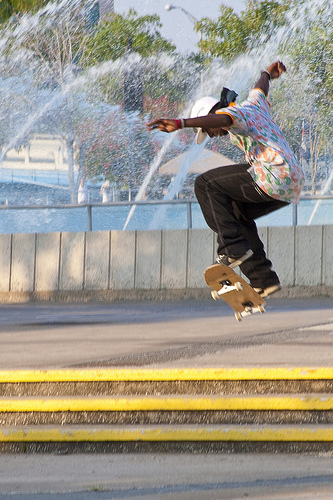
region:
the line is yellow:
[187, 432, 192, 433]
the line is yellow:
[180, 430, 189, 442]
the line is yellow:
[174, 436, 180, 442]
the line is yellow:
[199, 431, 204, 440]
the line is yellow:
[198, 429, 207, 438]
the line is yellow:
[194, 424, 205, 442]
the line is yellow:
[195, 432, 200, 434]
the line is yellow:
[191, 428, 200, 437]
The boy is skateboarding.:
[132, 54, 317, 328]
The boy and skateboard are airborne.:
[128, 62, 319, 326]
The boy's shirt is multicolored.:
[212, 82, 314, 214]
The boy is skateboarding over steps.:
[1, 356, 331, 461]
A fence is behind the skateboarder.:
[0, 218, 330, 304]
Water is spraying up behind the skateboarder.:
[0, 3, 332, 227]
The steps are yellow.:
[0, 360, 331, 456]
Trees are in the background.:
[0, 0, 332, 98]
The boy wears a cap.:
[177, 78, 232, 151]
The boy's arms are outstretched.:
[127, 43, 295, 156]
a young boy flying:
[141, 54, 307, 451]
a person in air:
[144, 60, 304, 325]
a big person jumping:
[166, 3, 281, 316]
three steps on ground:
[40, 353, 332, 461]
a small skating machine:
[194, 257, 265, 331]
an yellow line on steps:
[36, 371, 331, 389]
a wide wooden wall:
[34, 241, 320, 321]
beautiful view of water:
[41, 187, 331, 234]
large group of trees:
[60, 11, 327, 92]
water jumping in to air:
[35, 70, 196, 209]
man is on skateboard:
[154, 84, 284, 319]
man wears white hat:
[181, 101, 234, 143]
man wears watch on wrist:
[251, 68, 273, 83]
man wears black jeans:
[190, 150, 299, 269]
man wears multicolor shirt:
[199, 83, 324, 237]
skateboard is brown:
[192, 260, 274, 330]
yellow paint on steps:
[11, 368, 331, 450]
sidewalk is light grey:
[6, 288, 323, 363]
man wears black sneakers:
[202, 251, 255, 269]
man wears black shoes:
[215, 249, 284, 304]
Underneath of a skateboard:
[202, 263, 267, 322]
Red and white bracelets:
[173, 117, 186, 130]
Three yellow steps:
[2, 367, 331, 445]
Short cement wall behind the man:
[3, 226, 171, 292]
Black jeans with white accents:
[193, 161, 281, 254]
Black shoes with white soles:
[214, 250, 262, 266]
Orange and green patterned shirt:
[223, 93, 304, 201]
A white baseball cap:
[185, 91, 218, 145]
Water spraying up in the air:
[1, 10, 148, 231]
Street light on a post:
[157, 1, 206, 96]